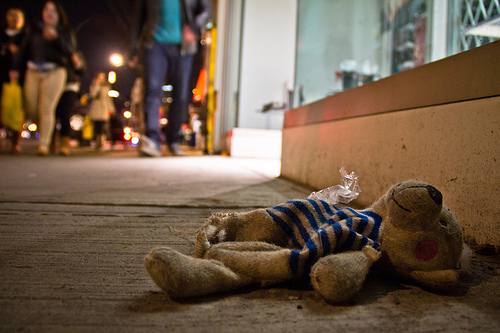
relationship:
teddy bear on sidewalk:
[144, 166, 464, 304] [17, 174, 395, 330]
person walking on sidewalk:
[1, 8, 31, 148] [0, 150, 499, 331]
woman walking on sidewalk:
[21, 0, 69, 152] [0, 150, 499, 331]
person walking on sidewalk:
[86, 68, 116, 148] [0, 150, 499, 331]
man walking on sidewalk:
[136, 1, 215, 157] [0, 150, 499, 331]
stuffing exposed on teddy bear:
[308, 167, 361, 203] [144, 166, 464, 304]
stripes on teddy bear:
[269, 195, 382, 271] [144, 166, 464, 304]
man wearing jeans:
[136, 1, 215, 157] [139, 36, 192, 138]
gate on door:
[448, 1, 498, 55] [431, 0, 499, 62]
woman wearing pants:
[21, 0, 69, 152] [25, 69, 67, 146]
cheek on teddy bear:
[414, 238, 439, 260] [144, 166, 464, 304]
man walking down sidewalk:
[136, 1, 215, 157] [0, 150, 499, 331]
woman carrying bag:
[21, 0, 69, 152] [66, 46, 81, 72]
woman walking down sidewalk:
[21, 0, 69, 152] [0, 150, 499, 331]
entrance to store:
[229, 2, 297, 176] [231, 1, 499, 247]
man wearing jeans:
[136, 1, 215, 157] [142, 42, 193, 146]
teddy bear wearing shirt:
[144, 166, 464, 304] [265, 196, 383, 269]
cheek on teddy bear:
[409, 230, 439, 260] [144, 166, 464, 304]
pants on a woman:
[25, 69, 67, 146] [16, 1, 72, 153]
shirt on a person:
[152, 3, 184, 42] [126, 1, 206, 156]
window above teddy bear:
[289, 3, 498, 108] [144, 166, 464, 304]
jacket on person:
[126, 2, 208, 53] [126, 1, 206, 156]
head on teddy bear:
[374, 180, 477, 294] [146, 180, 474, 303]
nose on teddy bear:
[428, 185, 443, 203] [146, 180, 474, 303]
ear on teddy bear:
[412, 268, 462, 290] [146, 180, 474, 303]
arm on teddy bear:
[311, 250, 376, 301] [146, 180, 474, 303]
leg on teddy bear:
[146, 242, 240, 302] [146, 180, 474, 303]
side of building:
[223, 0, 303, 133] [214, 4, 384, 164]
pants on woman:
[25, 69, 67, 146] [7, 4, 77, 155]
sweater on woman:
[12, 21, 77, 69] [22, 2, 82, 152]